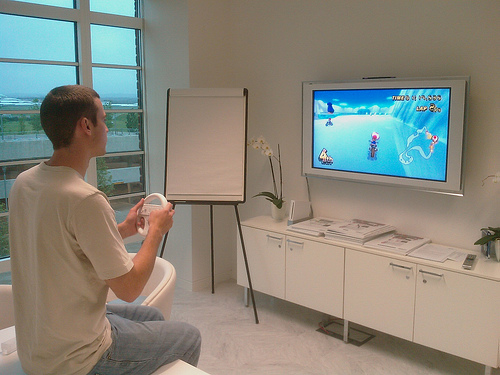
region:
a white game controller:
[128, 190, 172, 234]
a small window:
[91, 26, 138, 62]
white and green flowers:
[245, 132, 284, 214]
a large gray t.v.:
[292, 78, 471, 198]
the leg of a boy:
[93, 316, 200, 373]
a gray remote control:
[458, 248, 477, 272]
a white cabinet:
[347, 251, 419, 338]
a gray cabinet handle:
[387, 262, 414, 271]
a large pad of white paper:
[163, 87, 244, 195]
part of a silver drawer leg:
[340, 321, 351, 345]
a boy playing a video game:
[4, 67, 465, 373]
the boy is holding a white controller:
[8, 80, 209, 372]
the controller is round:
[127, 183, 180, 238]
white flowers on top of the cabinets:
[231, 132, 498, 373]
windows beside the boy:
[0, 1, 211, 373]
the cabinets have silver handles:
[232, 205, 497, 368]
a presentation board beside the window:
[141, 68, 268, 332]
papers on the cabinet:
[271, 200, 481, 305]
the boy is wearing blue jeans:
[9, 88, 209, 373]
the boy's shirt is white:
[7, 79, 208, 374]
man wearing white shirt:
[25, 65, 200, 371]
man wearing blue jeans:
[16, 71, 191, 367]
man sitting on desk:
[16, 57, 216, 372]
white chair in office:
[147, 245, 193, 310]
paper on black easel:
[150, 77, 257, 268]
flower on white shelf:
[245, 116, 307, 213]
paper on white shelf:
[326, 195, 391, 266]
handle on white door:
[381, 258, 451, 293]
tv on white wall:
[291, 60, 484, 211]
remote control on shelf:
[458, 232, 476, 283]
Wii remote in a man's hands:
[131, 193, 175, 238]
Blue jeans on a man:
[87, 280, 203, 369]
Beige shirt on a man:
[10, 151, 135, 366]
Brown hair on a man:
[31, 81, 115, 158]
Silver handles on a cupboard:
[253, 222, 316, 265]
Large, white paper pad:
[153, 80, 253, 212]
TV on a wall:
[285, 73, 471, 195]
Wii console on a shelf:
[286, 196, 317, 228]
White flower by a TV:
[240, 126, 302, 226]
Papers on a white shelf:
[310, 208, 470, 278]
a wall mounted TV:
[300, 80, 469, 194]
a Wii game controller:
[136, 192, 168, 235]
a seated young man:
[8, 83, 200, 371]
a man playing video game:
[8, 84, 203, 373]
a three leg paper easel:
[151, 84, 258, 321]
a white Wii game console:
[287, 197, 312, 227]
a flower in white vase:
[245, 133, 285, 224]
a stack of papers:
[284, 217, 341, 237]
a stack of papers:
[322, 218, 393, 245]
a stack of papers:
[363, 230, 430, 257]